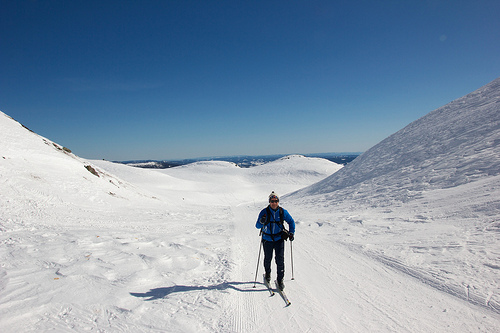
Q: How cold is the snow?
A: Very cold.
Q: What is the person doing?
A: Skiing.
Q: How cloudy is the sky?
A: Not very cloudy.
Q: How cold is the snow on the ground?
A: Very cold.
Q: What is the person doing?
A: Skiing.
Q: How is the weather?
A: Cold and clear.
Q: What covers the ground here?
A: Snow.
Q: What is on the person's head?
A: Ski cap.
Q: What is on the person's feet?
A: Skis.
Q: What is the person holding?
A: Ski poles.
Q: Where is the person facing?
A: The camera.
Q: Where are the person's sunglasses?
A: On their face.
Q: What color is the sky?
A: Blue.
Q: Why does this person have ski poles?
A: They are skiing.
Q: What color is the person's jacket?
A: Blue.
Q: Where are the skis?
A: On the person's feet.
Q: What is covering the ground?
A: Snow.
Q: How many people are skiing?
A: One.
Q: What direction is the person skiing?
A: Forward.